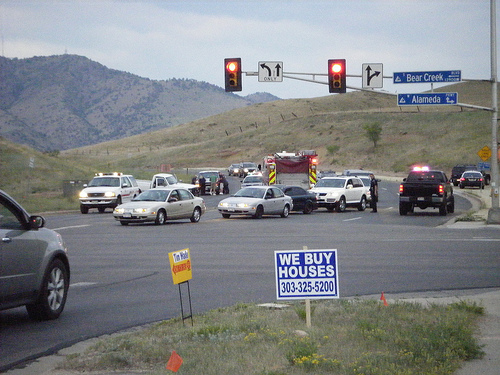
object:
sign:
[274, 249, 340, 301]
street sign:
[398, 94, 457, 104]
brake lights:
[439, 185, 444, 192]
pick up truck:
[399, 170, 455, 216]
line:
[343, 215, 366, 223]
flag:
[276, 158, 309, 172]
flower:
[302, 357, 308, 368]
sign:
[168, 247, 194, 285]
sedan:
[218, 185, 294, 220]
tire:
[156, 209, 167, 225]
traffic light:
[227, 63, 236, 72]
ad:
[276, 253, 336, 297]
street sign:
[393, 71, 463, 83]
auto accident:
[192, 171, 230, 197]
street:
[0, 167, 499, 373]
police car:
[77, 171, 142, 214]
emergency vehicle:
[268, 151, 318, 188]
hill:
[0, 49, 288, 151]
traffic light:
[331, 64, 342, 73]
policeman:
[199, 174, 206, 195]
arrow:
[172, 260, 192, 275]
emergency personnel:
[221, 173, 230, 194]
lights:
[95, 170, 125, 177]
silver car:
[2, 187, 71, 321]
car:
[269, 185, 318, 214]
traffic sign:
[362, 63, 384, 88]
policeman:
[369, 173, 380, 213]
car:
[113, 187, 206, 225]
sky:
[0, 0, 499, 100]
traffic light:
[225, 72, 242, 90]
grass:
[55, 299, 486, 374]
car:
[227, 163, 240, 176]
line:
[48, 223, 92, 230]